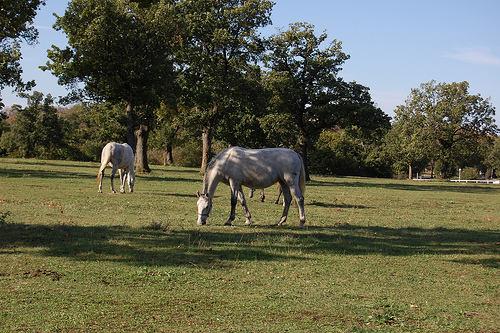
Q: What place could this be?
A: It is a pasture.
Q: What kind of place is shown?
A: It is a pasture.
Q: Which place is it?
A: It is a pasture.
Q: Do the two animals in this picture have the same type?
A: Yes, all the animals are horses.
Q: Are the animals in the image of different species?
A: No, all the animals are horses.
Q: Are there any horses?
A: Yes, there is a horse.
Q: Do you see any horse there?
A: Yes, there is a horse.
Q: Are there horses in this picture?
A: Yes, there is a horse.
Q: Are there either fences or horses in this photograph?
A: Yes, there is a horse.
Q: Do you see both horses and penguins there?
A: No, there is a horse but no penguins.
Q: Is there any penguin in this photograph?
A: No, there are no penguins.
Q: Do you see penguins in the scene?
A: No, there are no penguins.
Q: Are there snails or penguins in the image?
A: No, there are no penguins or snails.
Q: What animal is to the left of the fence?
A: The animal is a horse.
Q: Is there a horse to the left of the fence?
A: Yes, there is a horse to the left of the fence.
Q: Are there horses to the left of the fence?
A: Yes, there is a horse to the left of the fence.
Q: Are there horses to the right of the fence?
A: No, the horse is to the left of the fence.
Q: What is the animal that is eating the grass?
A: The animal is a horse.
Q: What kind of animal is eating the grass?
A: The animal is a horse.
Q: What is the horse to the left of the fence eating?
A: The horse is eating grass.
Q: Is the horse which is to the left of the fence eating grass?
A: Yes, the horse is eating grass.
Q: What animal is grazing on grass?
A: The horse is grazing on grass.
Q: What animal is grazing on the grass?
A: The horse is grazing on grass.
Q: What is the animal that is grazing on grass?
A: The animal is a horse.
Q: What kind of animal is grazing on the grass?
A: The animal is a horse.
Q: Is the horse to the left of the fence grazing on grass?
A: Yes, the horse is grazing on grass.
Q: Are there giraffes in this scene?
A: No, there are no giraffes.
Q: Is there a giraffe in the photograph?
A: No, there are no giraffes.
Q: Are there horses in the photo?
A: Yes, there is a horse.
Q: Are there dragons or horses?
A: Yes, there is a horse.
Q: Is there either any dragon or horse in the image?
A: Yes, there is a horse.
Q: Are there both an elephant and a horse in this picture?
A: No, there is a horse but no elephants.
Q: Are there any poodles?
A: No, there are no poodles.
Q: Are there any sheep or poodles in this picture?
A: No, there are no poodles or sheep.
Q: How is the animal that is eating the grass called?
A: The animal is a horse.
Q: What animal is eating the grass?
A: The animal is a horse.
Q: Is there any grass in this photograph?
A: Yes, there is grass.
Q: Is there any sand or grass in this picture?
A: Yes, there is grass.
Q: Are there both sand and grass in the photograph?
A: No, there is grass but no sand.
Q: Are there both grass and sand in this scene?
A: No, there is grass but no sand.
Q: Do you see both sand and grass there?
A: No, there is grass but no sand.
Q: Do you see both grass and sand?
A: No, there is grass but no sand.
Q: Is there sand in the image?
A: No, there is no sand.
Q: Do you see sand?
A: No, there is no sand.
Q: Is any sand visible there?
A: No, there is no sand.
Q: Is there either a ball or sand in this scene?
A: No, there are no sand or balls.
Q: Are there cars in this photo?
A: No, there are no cars.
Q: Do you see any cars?
A: No, there are no cars.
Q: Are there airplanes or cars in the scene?
A: No, there are no cars or airplanes.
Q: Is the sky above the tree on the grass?
A: Yes, the sky is above the tree.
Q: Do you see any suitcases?
A: No, there are no suitcases.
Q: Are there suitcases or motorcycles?
A: No, there are no suitcases or motorcycles.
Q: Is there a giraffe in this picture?
A: No, there are no giraffes.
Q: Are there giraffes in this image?
A: No, there are no giraffes.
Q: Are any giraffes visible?
A: No, there are no giraffes.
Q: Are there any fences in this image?
A: Yes, there is a fence.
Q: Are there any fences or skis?
A: Yes, there is a fence.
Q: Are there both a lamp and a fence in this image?
A: No, there is a fence but no lamps.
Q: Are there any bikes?
A: No, there are no bikes.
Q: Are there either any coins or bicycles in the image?
A: No, there are no bicycles or coins.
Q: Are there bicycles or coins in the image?
A: No, there are no bicycles or coins.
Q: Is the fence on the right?
A: Yes, the fence is on the right of the image.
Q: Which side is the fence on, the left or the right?
A: The fence is on the right of the image.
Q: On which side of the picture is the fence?
A: The fence is on the right of the image.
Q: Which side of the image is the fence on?
A: The fence is on the right of the image.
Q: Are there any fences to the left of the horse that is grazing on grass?
A: No, the fence is to the right of the horse.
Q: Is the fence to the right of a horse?
A: Yes, the fence is to the right of a horse.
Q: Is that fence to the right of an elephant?
A: No, the fence is to the right of a horse.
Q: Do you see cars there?
A: No, there are no cars.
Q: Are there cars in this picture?
A: No, there are no cars.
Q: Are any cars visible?
A: No, there are no cars.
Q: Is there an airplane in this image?
A: No, there are no airplanes.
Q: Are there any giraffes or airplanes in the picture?
A: No, there are no airplanes or giraffes.